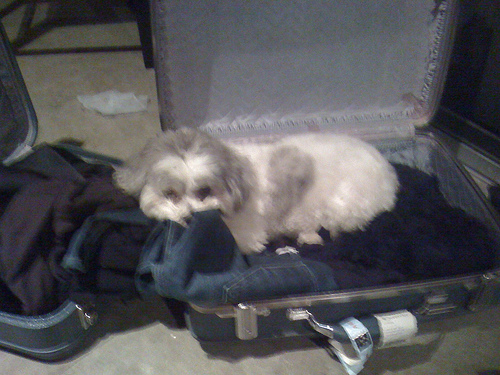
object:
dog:
[114, 126, 400, 255]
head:
[113, 128, 256, 228]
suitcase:
[152, 0, 499, 342]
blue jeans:
[60, 206, 338, 309]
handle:
[285, 294, 458, 341]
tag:
[328, 316, 375, 374]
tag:
[372, 309, 418, 350]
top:
[152, 1, 449, 140]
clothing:
[272, 161, 500, 291]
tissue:
[76, 90, 147, 116]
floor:
[2, 2, 499, 374]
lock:
[234, 302, 258, 340]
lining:
[373, 137, 495, 230]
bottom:
[184, 130, 499, 342]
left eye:
[197, 186, 211, 201]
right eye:
[164, 189, 177, 199]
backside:
[294, 131, 399, 209]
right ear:
[217, 146, 256, 212]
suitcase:
[0, 23, 126, 362]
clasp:
[76, 301, 99, 330]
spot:
[263, 145, 315, 224]